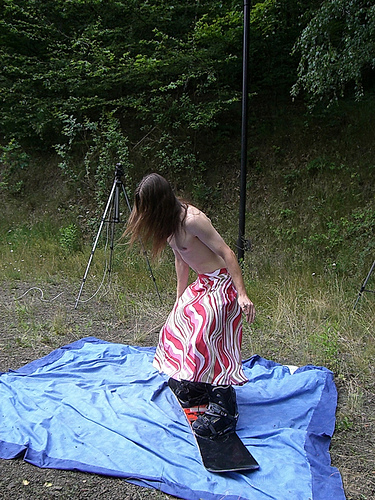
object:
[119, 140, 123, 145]
leaf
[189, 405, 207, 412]
letters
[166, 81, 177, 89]
leaf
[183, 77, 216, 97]
stem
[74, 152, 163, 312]
x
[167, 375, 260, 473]
snowboard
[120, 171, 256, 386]
man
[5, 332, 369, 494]
blanket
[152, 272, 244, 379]
skirt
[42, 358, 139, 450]
back ground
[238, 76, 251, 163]
sentence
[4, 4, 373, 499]
photo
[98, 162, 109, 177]
leaf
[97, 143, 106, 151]
leaf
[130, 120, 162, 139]
stem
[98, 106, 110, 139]
stem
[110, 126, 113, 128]
leaf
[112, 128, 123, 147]
stem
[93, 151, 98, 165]
stem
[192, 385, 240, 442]
boot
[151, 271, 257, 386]
half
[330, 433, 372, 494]
ground